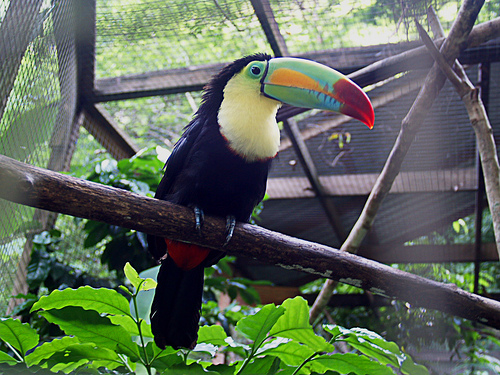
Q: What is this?
A: Parrot.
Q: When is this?
A: Daytime.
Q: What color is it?
A: Black.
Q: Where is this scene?
A: At a zoo.